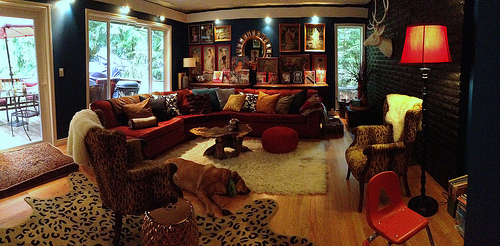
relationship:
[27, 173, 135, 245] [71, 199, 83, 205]
carpet has print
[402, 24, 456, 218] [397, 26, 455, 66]
lamp has shade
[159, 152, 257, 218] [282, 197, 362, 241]
dog on top of floor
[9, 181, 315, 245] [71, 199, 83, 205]
rug has print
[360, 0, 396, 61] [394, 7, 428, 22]
head on top of wall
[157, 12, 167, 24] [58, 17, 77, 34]
light on top of wall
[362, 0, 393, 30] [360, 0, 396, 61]
antlers on animal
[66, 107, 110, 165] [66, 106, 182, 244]
blanket on top of chair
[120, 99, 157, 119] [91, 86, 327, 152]
pillow on top of couch